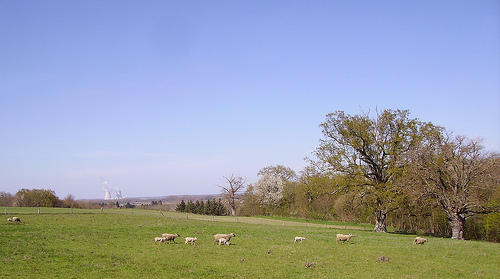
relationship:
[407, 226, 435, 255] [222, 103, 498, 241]
sheep between trees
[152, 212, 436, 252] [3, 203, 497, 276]
animals are in grass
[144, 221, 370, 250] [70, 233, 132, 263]
animals on grass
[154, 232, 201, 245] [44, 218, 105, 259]
animals walking grass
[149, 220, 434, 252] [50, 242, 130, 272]
sheep in grass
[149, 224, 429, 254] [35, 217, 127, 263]
sheep in grass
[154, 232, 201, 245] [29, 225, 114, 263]
animals in grass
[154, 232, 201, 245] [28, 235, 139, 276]
animals in grass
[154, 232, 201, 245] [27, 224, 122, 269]
animals in grass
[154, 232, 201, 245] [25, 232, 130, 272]
animals in grass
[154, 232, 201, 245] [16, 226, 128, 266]
animals in grass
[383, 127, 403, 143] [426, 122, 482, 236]
leaves on tree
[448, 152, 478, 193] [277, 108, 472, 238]
branches on tree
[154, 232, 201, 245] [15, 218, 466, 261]
animals walking in the pasture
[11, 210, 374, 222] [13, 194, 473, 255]
posts in the field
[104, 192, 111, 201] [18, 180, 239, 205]
building in the far off distance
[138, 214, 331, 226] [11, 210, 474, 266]
pathway on the side of grass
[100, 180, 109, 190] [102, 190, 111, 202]
smoke coming out of the building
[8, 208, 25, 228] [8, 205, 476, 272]
sheep laying on the grass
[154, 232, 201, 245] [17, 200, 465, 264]
animals in the field